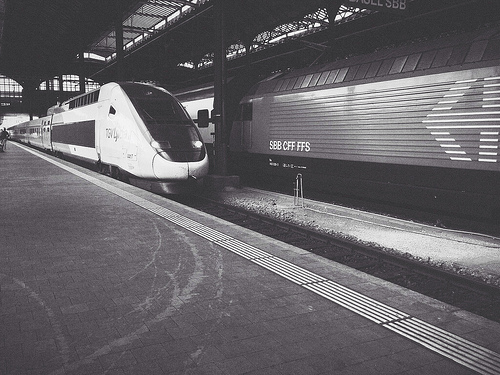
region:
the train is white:
[65, 77, 295, 307]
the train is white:
[107, 72, 207, 237]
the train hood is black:
[105, 74, 277, 214]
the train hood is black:
[97, 80, 333, 285]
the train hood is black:
[135, 116, 271, 286]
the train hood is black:
[80, 26, 220, 132]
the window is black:
[57, 92, 155, 223]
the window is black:
[65, 104, 129, 195]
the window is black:
[60, 86, 217, 316]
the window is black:
[72, 103, 87, 143]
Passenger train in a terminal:
[1, 77, 241, 192]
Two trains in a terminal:
[4, 48, 498, 215]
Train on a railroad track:
[3, 80, 497, 335]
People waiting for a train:
[0, 113, 17, 164]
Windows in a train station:
[2, 61, 109, 111]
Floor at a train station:
[6, 173, 409, 373]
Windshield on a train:
[108, 67, 220, 224]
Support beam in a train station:
[190, 12, 257, 229]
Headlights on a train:
[136, 130, 221, 173]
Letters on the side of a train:
[247, 124, 332, 175]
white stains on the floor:
[182, 304, 194, 326]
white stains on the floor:
[165, 281, 187, 317]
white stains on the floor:
[179, 288, 190, 307]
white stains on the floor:
[170, 295, 172, 299]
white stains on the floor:
[184, 282, 196, 315]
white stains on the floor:
[170, 299, 177, 308]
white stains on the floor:
[187, 287, 199, 306]